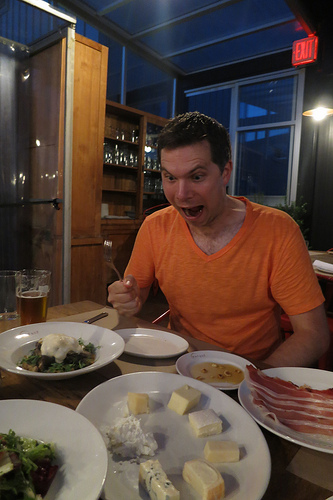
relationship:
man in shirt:
[108, 112, 329, 369] [117, 205, 325, 349]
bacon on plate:
[248, 366, 331, 427] [237, 362, 329, 451]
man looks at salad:
[108, 112, 329, 369] [19, 335, 97, 375]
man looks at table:
[108, 112, 329, 369] [6, 288, 323, 487]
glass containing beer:
[12, 267, 50, 324] [16, 290, 49, 325]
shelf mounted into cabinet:
[102, 162, 138, 171] [104, 99, 170, 287]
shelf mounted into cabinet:
[104, 135, 140, 148] [104, 99, 170, 287]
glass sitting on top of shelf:
[104, 141, 111, 162] [102, 162, 138, 171]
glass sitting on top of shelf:
[114, 142, 120, 164] [102, 162, 138, 171]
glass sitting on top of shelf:
[129, 147, 135, 166] [102, 162, 138, 171]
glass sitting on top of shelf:
[130, 125, 136, 143] [104, 135, 140, 148]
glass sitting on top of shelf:
[120, 127, 126, 140] [104, 135, 140, 148]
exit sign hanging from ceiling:
[288, 32, 317, 66] [54, 0, 322, 79]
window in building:
[185, 84, 314, 194] [3, 1, 322, 324]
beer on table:
[16, 290, 47, 324] [6, 300, 245, 458]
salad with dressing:
[17, 321, 121, 380] [32, 321, 82, 353]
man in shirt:
[108, 112, 329, 369] [127, 198, 321, 348]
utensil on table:
[90, 311, 114, 324] [3, 297, 233, 401]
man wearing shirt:
[108, 112, 329, 369] [109, 188, 322, 352]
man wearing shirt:
[100, 112, 319, 379] [109, 188, 322, 352]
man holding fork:
[108, 112, 329, 369] [99, 251, 124, 283]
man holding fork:
[108, 112, 329, 369] [89, 241, 128, 300]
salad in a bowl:
[4, 426, 53, 480] [8, 399, 116, 495]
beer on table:
[15, 270, 51, 322] [38, 284, 190, 437]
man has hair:
[108, 112, 329, 369] [154, 105, 208, 146]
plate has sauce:
[174, 348, 257, 390] [188, 360, 242, 384]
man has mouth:
[108, 112, 329, 369] [174, 202, 204, 219]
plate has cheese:
[71, 369, 271, 499] [105, 383, 241, 499]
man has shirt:
[108, 112, 329, 369] [124, 196, 324, 359]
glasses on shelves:
[98, 124, 142, 170] [101, 110, 139, 218]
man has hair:
[108, 112, 329, 369] [152, 109, 233, 176]